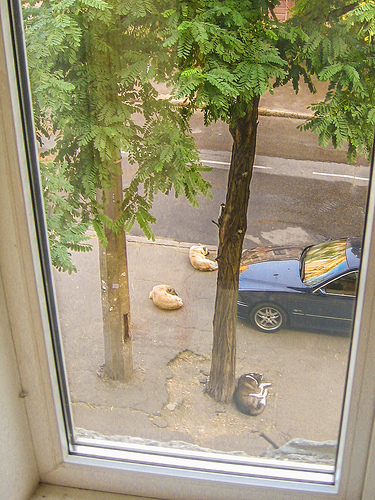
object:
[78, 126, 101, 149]
leaves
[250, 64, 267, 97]
leaves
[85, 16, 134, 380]
pole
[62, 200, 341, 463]
sidewalk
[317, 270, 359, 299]
window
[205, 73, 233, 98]
leaves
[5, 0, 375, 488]
window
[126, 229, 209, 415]
ground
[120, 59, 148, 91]
leaves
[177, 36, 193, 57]
leaves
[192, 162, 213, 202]
leaves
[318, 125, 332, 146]
leaves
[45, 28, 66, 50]
leaves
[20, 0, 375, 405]
tree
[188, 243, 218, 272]
dog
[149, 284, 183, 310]
dog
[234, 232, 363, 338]
car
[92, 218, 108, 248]
leaves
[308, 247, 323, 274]
reflection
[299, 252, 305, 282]
windshield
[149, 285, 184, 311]
lab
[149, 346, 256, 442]
crumbled surface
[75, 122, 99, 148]
leaves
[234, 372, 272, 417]
dog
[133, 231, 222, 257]
curb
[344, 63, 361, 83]
leaves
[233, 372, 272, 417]
sleeping